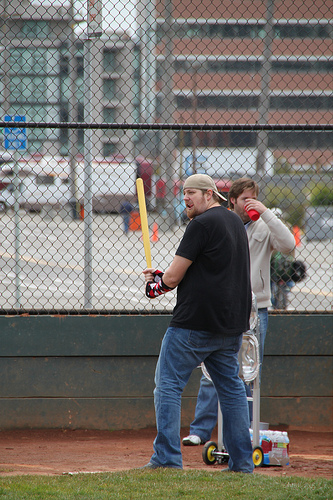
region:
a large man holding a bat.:
[124, 168, 267, 497]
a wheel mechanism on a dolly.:
[195, 440, 268, 472]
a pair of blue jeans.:
[140, 327, 256, 475]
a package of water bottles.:
[232, 422, 296, 471]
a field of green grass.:
[0, 466, 330, 498]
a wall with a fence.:
[0, 311, 332, 430]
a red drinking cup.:
[239, 204, 258, 223]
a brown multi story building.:
[146, 3, 332, 172]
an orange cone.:
[290, 222, 302, 248]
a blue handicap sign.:
[4, 113, 35, 314]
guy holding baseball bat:
[125, 168, 261, 486]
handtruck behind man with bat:
[120, 159, 290, 475]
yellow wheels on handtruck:
[197, 395, 280, 483]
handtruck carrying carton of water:
[209, 403, 326, 481]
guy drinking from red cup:
[209, 162, 297, 315]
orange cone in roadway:
[144, 216, 171, 251]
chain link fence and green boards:
[28, 185, 125, 407]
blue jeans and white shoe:
[184, 408, 227, 453]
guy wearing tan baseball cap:
[163, 163, 247, 242]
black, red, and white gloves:
[134, 263, 191, 306]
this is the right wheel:
[191, 430, 230, 473]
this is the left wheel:
[238, 439, 266, 467]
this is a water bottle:
[278, 426, 289, 458]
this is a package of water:
[238, 413, 310, 483]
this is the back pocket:
[188, 315, 216, 346]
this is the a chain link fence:
[6, 294, 36, 305]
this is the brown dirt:
[42, 443, 66, 459]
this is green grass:
[160, 473, 177, 492]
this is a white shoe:
[177, 426, 216, 460]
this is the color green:
[63, 320, 81, 338]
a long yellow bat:
[132, 175, 157, 265]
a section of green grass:
[0, 468, 332, 499]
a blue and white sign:
[1, 114, 29, 304]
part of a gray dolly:
[199, 381, 266, 468]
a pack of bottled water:
[251, 426, 291, 467]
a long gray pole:
[77, 26, 99, 309]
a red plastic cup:
[244, 202, 262, 220]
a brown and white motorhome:
[0, 157, 137, 218]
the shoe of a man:
[181, 432, 203, 445]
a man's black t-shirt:
[168, 206, 254, 332]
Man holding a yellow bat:
[116, 159, 263, 462]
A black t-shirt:
[159, 206, 266, 346]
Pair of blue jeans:
[138, 316, 270, 484]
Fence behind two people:
[3, 2, 331, 321]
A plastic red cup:
[237, 195, 266, 227]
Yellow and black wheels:
[196, 434, 270, 475]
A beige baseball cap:
[174, 167, 232, 206]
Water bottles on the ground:
[241, 419, 298, 474]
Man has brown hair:
[225, 171, 266, 226]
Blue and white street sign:
[1, 107, 32, 168]